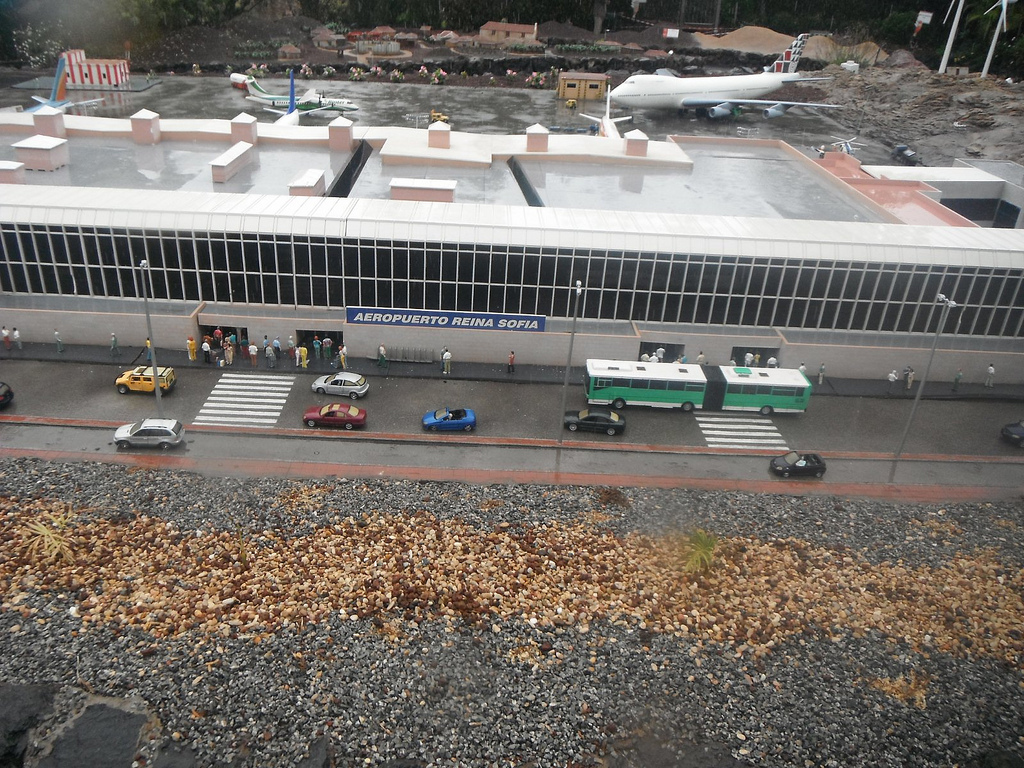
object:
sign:
[343, 307, 545, 334]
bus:
[584, 358, 812, 417]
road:
[0, 340, 1024, 491]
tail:
[767, 34, 811, 73]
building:
[61, 48, 129, 85]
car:
[562, 409, 625, 436]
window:
[668, 262, 687, 292]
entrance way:
[197, 324, 251, 355]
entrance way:
[295, 328, 342, 361]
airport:
[0, 72, 1019, 228]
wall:
[0, 289, 1024, 386]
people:
[375, 343, 388, 368]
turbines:
[936, 0, 1015, 79]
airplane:
[246, 69, 363, 117]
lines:
[692, 410, 791, 453]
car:
[310, 371, 368, 401]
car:
[302, 403, 367, 430]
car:
[770, 450, 827, 477]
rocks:
[0, 454, 1022, 768]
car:
[421, 406, 476, 431]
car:
[115, 364, 176, 394]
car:
[113, 418, 185, 449]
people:
[312, 336, 321, 360]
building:
[0, 112, 1024, 385]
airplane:
[610, 34, 845, 121]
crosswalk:
[191, 373, 297, 429]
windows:
[246, 274, 263, 305]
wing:
[681, 98, 846, 119]